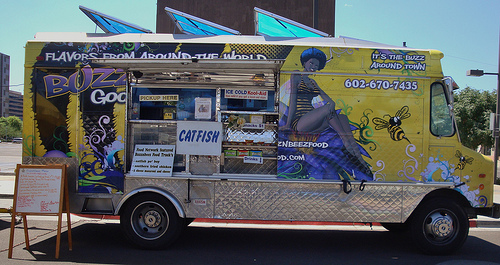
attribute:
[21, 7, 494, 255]
truck — designed, yellow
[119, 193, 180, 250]
rear wheel — black, rubber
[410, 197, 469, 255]
front wheel — black, rubber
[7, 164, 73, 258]
menu board — white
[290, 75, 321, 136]
swimsuit — striped, black, yellow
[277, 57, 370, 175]
woman — black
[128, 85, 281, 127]
side window — small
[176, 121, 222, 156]
sign — white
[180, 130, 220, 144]
writing — blue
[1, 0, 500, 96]
sky — white, blue, pale blue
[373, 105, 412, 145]
bee — painted, large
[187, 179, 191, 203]
strap — black, dangling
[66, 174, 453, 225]
panel — stainless steel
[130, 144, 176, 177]
lower sign — white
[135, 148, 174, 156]
lower writing — black